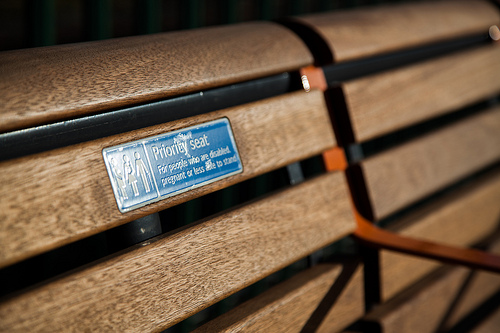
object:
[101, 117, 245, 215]
sign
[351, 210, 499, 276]
armrest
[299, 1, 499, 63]
slat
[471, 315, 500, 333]
slat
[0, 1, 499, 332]
backrest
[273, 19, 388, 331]
joint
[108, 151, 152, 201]
drawing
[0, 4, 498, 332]
backplate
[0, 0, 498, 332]
seats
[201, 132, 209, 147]
letters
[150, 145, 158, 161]
letters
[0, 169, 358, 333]
bench slat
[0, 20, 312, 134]
bench slat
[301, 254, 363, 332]
shadow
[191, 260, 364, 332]
bench slat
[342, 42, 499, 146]
bench slat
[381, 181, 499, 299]
bench slat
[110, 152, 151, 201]
logo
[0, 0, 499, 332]
background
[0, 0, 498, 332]
bench